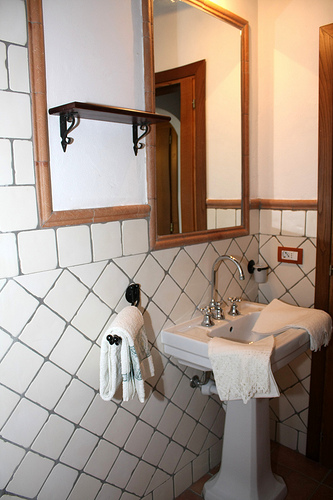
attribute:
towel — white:
[99, 305, 154, 400]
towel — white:
[251, 295, 331, 349]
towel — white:
[208, 335, 280, 401]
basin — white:
[207, 309, 289, 344]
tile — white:
[17, 302, 68, 361]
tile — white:
[52, 375, 98, 429]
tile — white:
[24, 412, 75, 465]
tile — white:
[100, 405, 137, 451]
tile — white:
[16, 229, 58, 273]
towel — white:
[98, 284, 156, 406]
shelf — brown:
[47, 101, 171, 153]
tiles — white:
[66, 406, 142, 484]